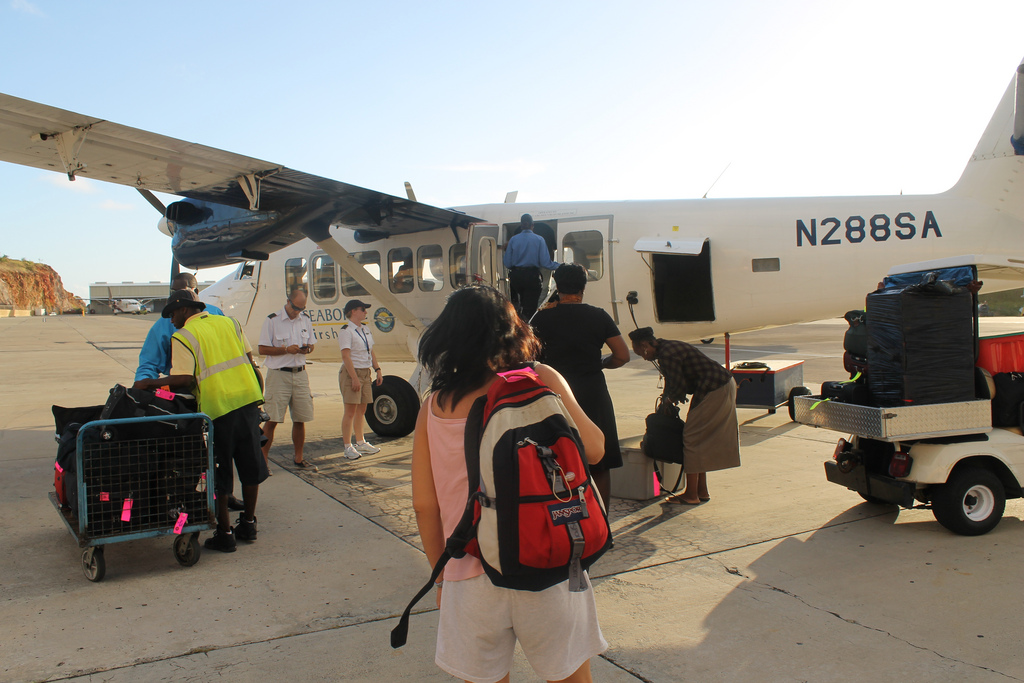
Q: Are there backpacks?
A: Yes, there is a backpack.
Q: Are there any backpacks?
A: Yes, there is a backpack.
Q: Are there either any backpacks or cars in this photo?
A: Yes, there is a backpack.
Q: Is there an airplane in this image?
A: Yes, there is an airplane.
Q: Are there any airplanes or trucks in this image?
A: Yes, there is an airplane.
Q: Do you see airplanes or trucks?
A: Yes, there is an airplane.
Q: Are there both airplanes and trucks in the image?
A: No, there is an airplane but no trucks.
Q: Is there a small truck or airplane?
A: Yes, there is a small airplane.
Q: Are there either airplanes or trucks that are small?
A: Yes, the airplane is small.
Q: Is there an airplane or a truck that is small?
A: Yes, the airplane is small.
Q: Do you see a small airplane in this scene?
A: Yes, there is a small airplane.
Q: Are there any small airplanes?
A: Yes, there is a small airplane.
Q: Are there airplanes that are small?
A: Yes, there is an airplane that is small.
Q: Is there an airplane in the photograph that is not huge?
A: Yes, there is a small airplane.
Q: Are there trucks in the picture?
A: No, there are no trucks.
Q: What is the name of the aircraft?
A: The aircraft is an airplane.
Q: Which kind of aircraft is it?
A: The aircraft is an airplane.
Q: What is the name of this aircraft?
A: That is an airplane.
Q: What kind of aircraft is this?
A: That is an airplane.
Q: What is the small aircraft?
A: The aircraft is an airplane.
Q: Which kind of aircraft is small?
A: The aircraft is an airplane.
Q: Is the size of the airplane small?
A: Yes, the airplane is small.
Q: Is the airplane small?
A: Yes, the airplane is small.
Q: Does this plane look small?
A: Yes, the plane is small.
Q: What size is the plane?
A: The plane is small.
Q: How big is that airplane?
A: The airplane is small.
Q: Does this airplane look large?
A: No, the airplane is small.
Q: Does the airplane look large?
A: No, the airplane is small.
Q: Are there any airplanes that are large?
A: No, there is an airplane but it is small.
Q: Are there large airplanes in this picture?
A: No, there is an airplane but it is small.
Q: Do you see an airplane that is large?
A: No, there is an airplane but it is small.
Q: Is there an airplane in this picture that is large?
A: No, there is an airplane but it is small.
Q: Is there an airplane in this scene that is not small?
A: No, there is an airplane but it is small.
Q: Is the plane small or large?
A: The plane is small.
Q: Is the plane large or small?
A: The plane is small.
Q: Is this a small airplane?
A: Yes, this is a small airplane.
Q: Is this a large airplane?
A: No, this is a small airplane.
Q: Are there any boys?
A: No, there are no boys.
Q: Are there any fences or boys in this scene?
A: No, there are no boys or fences.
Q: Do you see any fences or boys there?
A: No, there are no boys or fences.